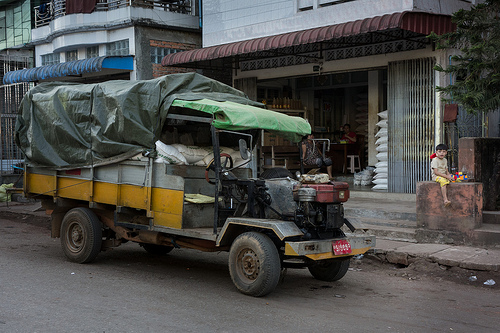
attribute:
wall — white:
[213, 8, 275, 32]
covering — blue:
[3, 55, 131, 86]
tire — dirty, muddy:
[227, 231, 279, 295]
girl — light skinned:
[434, 142, 449, 159]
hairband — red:
[430, 152, 435, 159]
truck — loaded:
[149, 133, 219, 170]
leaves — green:
[452, 33, 483, 90]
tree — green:
[428, 0, 498, 128]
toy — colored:
[449, 165, 474, 182]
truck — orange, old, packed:
[7, 59, 379, 306]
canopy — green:
[173, 83, 331, 155]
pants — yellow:
[434, 176, 452, 197]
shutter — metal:
[403, 73, 438, 155]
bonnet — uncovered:
[367, 46, 459, 197]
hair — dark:
[432, 140, 447, 152]